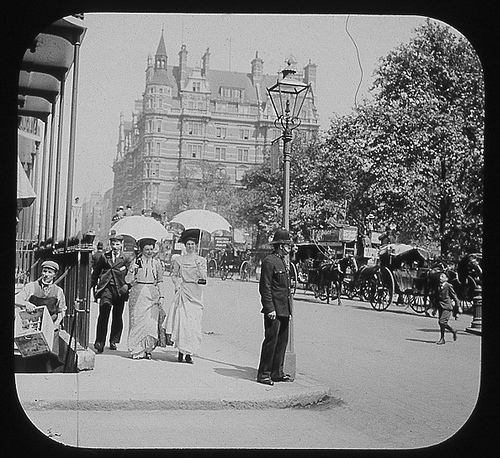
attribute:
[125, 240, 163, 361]
woman — walking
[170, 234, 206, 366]
woman — walking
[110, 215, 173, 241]
umbrella — open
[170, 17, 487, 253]
trees — tall